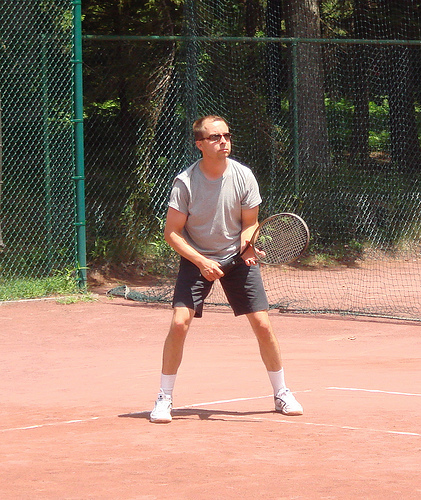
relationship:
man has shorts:
[148, 113, 301, 424] [150, 113, 305, 421]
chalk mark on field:
[0, 383, 331, 432] [5, 291, 419, 499]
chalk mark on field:
[322, 383, 420, 398] [5, 291, 419, 499]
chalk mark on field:
[186, 407, 419, 437] [5, 291, 419, 499]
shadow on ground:
[173, 403, 290, 428] [73, 364, 334, 452]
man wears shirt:
[148, 113, 301, 424] [159, 158, 265, 272]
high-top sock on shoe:
[268, 367, 286, 394] [275, 389, 302, 417]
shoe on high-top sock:
[150, 392, 175, 424] [161, 374, 175, 395]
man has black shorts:
[148, 113, 301, 424] [172, 251, 268, 316]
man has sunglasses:
[148, 113, 301, 424] [198, 129, 233, 141]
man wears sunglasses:
[148, 113, 301, 424] [209, 131, 231, 146]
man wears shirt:
[154, 98, 330, 411] [161, 156, 268, 266]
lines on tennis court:
[0, 382, 411, 451] [3, 295, 420, 499]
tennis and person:
[186, 210, 313, 280] [151, 115, 303, 421]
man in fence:
[148, 113, 301, 424] [36, 30, 420, 322]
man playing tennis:
[148, 113, 301, 424] [190, 207, 318, 268]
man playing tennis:
[148, 113, 301, 424] [199, 209, 313, 280]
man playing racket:
[148, 113, 301, 424] [199, 211, 311, 283]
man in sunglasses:
[148, 113, 301, 424] [196, 131, 237, 142]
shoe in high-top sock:
[273, 391, 303, 414] [266, 369, 286, 393]